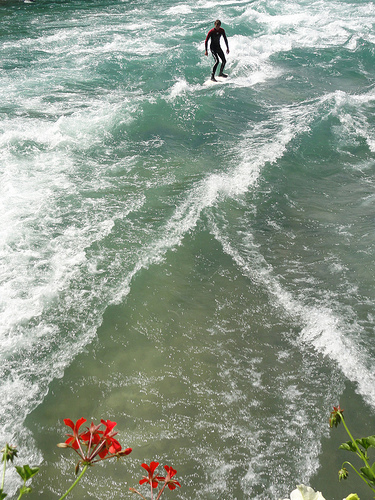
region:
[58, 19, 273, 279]
the man is surfing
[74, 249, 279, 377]
the waves are choppy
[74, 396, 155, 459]
the flowers are red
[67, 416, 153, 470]
the flowers are bright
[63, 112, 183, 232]
the water is blue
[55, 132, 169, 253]
the waves are white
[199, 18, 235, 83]
man wearing black wetsuit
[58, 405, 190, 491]
red flowers in foreground over water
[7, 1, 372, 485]
green and blue ocean water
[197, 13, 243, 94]
man standing on board surfing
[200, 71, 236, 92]
man on white surfboard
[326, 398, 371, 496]
green leaves of flowering plant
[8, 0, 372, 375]
white foam of waves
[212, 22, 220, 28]
short blond hair on surfer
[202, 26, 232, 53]
long sleeve red shirt on surfer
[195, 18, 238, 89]
man standing on white surfboard wearing black wetsuit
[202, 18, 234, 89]
person standing on a white surfboard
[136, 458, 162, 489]
small flower with bright red petals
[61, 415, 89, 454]
small flower with bright red petals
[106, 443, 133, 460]
small flower with bright red petals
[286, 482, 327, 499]
small flower with white petals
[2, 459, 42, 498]
stem of a plant with green leaves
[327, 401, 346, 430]
red flower with dropping petals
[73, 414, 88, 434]
bright red petal of a flower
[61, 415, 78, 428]
bright red petal of a flower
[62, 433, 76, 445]
bright red petal of a flower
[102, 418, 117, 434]
bright red petal of a flower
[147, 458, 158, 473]
bright red petal of a flower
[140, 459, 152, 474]
bright red petal of a flower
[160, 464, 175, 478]
bright red petal of a flower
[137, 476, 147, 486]
bright red petal of a flower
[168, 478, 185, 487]
bright red petal of a flower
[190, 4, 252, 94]
the man is surfing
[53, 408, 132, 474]
this is a flower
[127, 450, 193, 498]
this is a flower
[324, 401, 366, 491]
this is a flower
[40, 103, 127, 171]
this is a wave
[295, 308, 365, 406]
this is a wave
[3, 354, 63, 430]
this is a wave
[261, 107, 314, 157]
this is a wave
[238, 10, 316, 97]
this is a wave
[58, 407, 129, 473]
The red flower over the water.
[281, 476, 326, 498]
The white flower that is cut off.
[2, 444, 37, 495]
The plant in the far left corner.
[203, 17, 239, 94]
a person in the ocean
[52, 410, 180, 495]
red flowers over the water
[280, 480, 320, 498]
half a white flower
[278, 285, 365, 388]
white ocean foam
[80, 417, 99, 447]
a bright red flower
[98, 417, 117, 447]
a bright red flower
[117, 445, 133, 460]
a bright red flower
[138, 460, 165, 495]
a bright red flower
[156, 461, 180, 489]
a bright red flower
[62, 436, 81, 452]
a bright red flower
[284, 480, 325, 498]
a vivid white flower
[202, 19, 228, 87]
The man is on a surfboard.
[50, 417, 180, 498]
The flowers in the forefront are red in color.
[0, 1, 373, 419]
The water is not calm.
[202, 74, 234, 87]
The surfboard is in the water.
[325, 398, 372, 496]
The plant on the right is green in color.